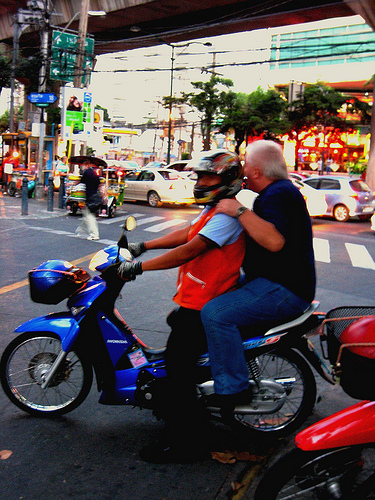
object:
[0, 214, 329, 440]
bike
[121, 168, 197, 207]
cars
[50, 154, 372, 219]
traffic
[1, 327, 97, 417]
tire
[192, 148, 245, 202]
helmet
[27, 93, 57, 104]
traffic sign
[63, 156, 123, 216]
food cart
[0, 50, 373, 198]
street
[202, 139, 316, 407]
man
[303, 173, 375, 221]
sedan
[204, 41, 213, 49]
light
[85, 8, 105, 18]
light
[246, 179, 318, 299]
tshirt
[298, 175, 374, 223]
hatchback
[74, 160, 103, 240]
man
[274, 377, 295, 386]
exhaust pipe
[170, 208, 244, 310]
vest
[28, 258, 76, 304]
basket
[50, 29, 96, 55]
sign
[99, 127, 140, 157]
station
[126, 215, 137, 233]
mirror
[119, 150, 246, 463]
man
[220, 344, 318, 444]
tire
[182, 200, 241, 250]
shirt